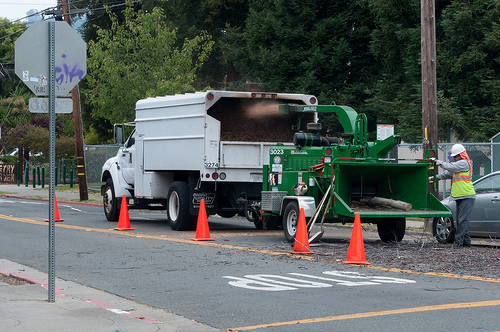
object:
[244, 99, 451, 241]
green lifter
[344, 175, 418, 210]
tree limbs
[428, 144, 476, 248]
city employee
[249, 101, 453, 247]
chipper truck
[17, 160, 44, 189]
posts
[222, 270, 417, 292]
stop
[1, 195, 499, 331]
street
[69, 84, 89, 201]
pole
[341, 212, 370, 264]
cone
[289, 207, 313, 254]
cone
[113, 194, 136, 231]
cone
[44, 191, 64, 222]
cone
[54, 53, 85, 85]
graffiti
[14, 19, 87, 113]
stop sign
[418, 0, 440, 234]
pole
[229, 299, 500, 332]
line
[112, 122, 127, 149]
mirror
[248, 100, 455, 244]
wood chipper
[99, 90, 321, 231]
truck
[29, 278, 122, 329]
concrete walkway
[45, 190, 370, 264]
cones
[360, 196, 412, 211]
limb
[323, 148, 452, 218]
lifter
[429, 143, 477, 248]
man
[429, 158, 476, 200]
reflective clothing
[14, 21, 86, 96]
sign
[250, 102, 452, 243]
truck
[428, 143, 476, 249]
street worker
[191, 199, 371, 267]
cones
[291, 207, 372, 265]
cones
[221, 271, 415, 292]
text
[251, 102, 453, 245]
trailer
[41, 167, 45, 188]
post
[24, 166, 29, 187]
post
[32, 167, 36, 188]
post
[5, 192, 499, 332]
road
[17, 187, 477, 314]
ground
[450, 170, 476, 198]
yellow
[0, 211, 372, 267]
line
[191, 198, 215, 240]
cone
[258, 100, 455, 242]
wood chipper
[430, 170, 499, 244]
car